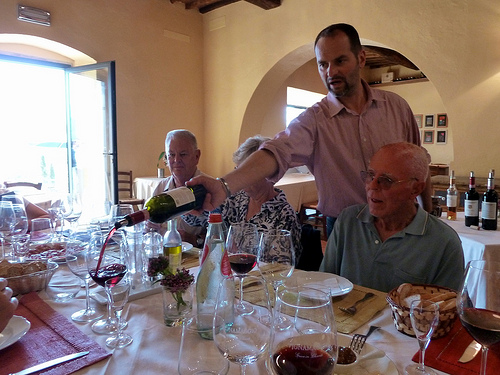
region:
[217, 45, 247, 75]
The wall is tan.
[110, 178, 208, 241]
A wine bottle.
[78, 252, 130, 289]
The wine is red.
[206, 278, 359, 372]
The glasses are clear.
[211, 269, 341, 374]
The glasses are made of glass.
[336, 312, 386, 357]
A fork.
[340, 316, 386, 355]
The fork is made of metal.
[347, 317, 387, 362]
The fork is gray.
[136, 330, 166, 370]
The tablecloth is white.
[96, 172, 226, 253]
The person is pouring wine.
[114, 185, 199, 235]
a green bottle of wine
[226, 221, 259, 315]
a glass of red wine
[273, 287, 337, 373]
a glass of red wine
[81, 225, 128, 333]
a glass of red wine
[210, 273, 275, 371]
a clear stemmed wine glass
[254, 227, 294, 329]
a clear stemmed wine glass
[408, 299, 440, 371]
a clear stemmed wine glass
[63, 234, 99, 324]
a clear stemmed wine glass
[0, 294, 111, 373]
a red placemat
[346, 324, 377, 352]
a silver fork utensil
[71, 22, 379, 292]
a man pouring wine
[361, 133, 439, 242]
a man wearing glasses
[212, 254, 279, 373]
a empty wine glass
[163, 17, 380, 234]
a man holding a wine bottle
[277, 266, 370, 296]
a white plate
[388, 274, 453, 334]
a bowl full of bread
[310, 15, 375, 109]
a man with facial hair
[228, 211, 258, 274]
a glass with wine in it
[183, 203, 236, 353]
a clear glass bottle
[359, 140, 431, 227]
a man with grey hair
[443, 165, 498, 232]
three bottles of wine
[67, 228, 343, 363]
several glasses for wine on a table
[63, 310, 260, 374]
white tablecloth underneath glasses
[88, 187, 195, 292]
pouring wine into a tall glass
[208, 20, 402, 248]
someone pouring wine into a glass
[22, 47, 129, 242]
a large open door with sunlight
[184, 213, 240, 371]
full bottle of water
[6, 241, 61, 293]
brown basket full of bread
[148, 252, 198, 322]
two flowers in a clear glass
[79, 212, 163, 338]
pouring wine into a tall glass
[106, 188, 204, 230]
A bottleof wine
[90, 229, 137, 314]
A glass of wine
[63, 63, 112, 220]
An open glass door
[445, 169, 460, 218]
A bottle of light wine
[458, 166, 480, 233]
A bottle of red wine.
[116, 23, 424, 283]
A man pouring a bottleof wine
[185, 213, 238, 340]
Bottle of seltzer water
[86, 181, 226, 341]
A bottle of wine being poured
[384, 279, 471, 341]
A basket of bread sticks.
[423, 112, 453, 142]
Some paintings.